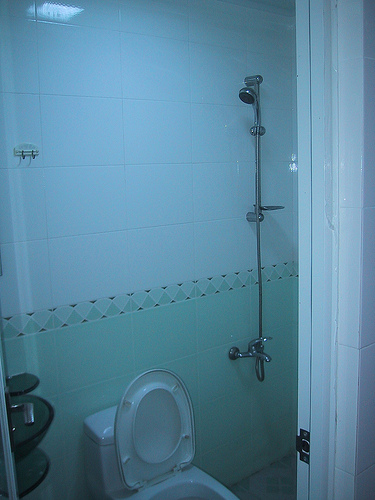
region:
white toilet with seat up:
[102, 360, 231, 495]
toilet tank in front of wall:
[77, 402, 119, 492]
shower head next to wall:
[229, 64, 272, 134]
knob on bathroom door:
[4, 393, 49, 430]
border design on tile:
[145, 276, 215, 309]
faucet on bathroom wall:
[225, 329, 278, 372]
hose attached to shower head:
[249, 249, 267, 318]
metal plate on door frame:
[293, 423, 313, 472]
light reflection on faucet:
[259, 352, 273, 366]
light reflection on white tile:
[28, 3, 85, 53]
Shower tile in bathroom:
[106, 226, 145, 256]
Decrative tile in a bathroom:
[83, 297, 193, 322]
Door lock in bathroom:
[284, 434, 323, 468]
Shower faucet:
[247, 337, 280, 373]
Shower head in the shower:
[238, 83, 268, 115]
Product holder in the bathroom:
[6, 363, 43, 498]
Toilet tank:
[84, 410, 113, 485]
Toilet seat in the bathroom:
[119, 375, 225, 470]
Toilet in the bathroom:
[154, 466, 210, 498]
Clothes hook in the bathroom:
[2, 125, 65, 177]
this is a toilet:
[98, 400, 201, 498]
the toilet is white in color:
[128, 401, 185, 498]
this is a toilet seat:
[121, 376, 192, 477]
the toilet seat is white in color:
[129, 388, 180, 472]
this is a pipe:
[258, 224, 262, 334]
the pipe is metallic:
[259, 145, 261, 334]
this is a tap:
[233, 340, 272, 363]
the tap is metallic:
[231, 347, 263, 360]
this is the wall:
[192, 308, 222, 389]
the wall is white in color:
[186, 320, 214, 379]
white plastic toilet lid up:
[113, 366, 199, 486]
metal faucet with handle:
[226, 332, 275, 363]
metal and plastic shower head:
[237, 85, 265, 128]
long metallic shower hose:
[249, 108, 271, 381]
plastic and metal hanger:
[13, 139, 40, 164]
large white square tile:
[41, 161, 128, 237]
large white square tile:
[118, 94, 192, 165]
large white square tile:
[125, 219, 197, 295]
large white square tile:
[120, 29, 191, 101]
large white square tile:
[34, 18, 127, 103]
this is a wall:
[58, 79, 182, 288]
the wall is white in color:
[55, 356, 97, 397]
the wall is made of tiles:
[85, 235, 193, 351]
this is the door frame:
[297, 248, 333, 496]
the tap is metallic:
[227, 335, 265, 367]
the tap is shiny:
[233, 348, 270, 363]